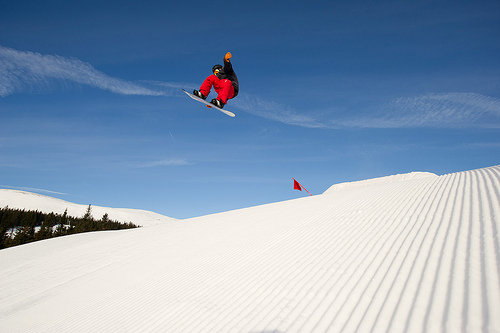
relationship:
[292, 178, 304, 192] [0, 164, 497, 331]
flag on slope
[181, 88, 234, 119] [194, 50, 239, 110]
snowboard under man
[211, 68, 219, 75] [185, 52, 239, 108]
goggles on man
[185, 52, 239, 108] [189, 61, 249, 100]
man in snowsuit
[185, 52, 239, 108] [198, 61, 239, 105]
man in snow suit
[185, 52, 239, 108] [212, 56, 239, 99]
man in jacket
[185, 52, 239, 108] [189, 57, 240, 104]
man in snowsuit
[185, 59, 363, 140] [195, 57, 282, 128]
man in suit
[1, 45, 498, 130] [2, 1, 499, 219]
cloud in sky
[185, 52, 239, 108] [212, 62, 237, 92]
man wearing jacket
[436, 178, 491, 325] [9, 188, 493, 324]
lines in snow